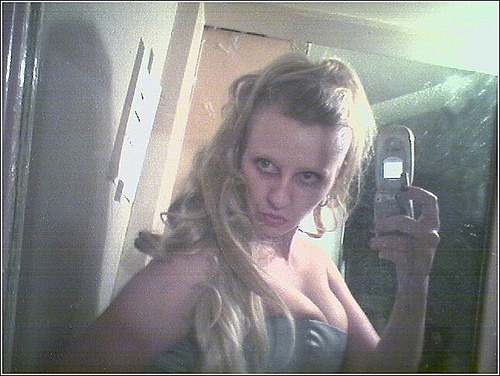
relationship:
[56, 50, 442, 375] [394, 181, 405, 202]
woman girl has on red nail polish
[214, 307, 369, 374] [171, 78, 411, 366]
top on woman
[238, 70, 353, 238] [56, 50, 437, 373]
head of woman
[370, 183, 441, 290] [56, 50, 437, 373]
hand of woman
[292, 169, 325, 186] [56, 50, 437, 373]
eye of woman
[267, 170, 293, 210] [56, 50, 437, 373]
nose of woman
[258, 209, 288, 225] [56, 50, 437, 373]
mouth of woman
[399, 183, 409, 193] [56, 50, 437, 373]
finger nail on woman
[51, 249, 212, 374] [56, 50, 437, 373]
arm on woman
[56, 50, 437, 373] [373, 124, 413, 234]
woman holding cell phone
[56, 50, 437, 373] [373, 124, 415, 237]
woman has cell phone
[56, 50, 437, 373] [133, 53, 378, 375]
woman has hair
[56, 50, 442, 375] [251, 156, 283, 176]
woman has eye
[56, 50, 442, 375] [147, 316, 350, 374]
woman wearing dress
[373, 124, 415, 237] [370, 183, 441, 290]
cell phone in hand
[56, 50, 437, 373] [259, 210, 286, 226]
woman wearing lipstick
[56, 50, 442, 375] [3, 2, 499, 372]
woman standing in doorway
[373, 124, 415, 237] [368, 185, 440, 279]
cell phone in hand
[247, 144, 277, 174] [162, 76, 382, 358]
eye of woman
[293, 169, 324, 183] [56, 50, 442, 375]
eye of woman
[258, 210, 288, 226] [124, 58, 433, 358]
mouth of woman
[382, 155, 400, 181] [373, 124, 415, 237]
screen on cell phone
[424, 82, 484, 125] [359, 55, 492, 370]
scratches on mirror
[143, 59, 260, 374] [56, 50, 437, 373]
hair on woman